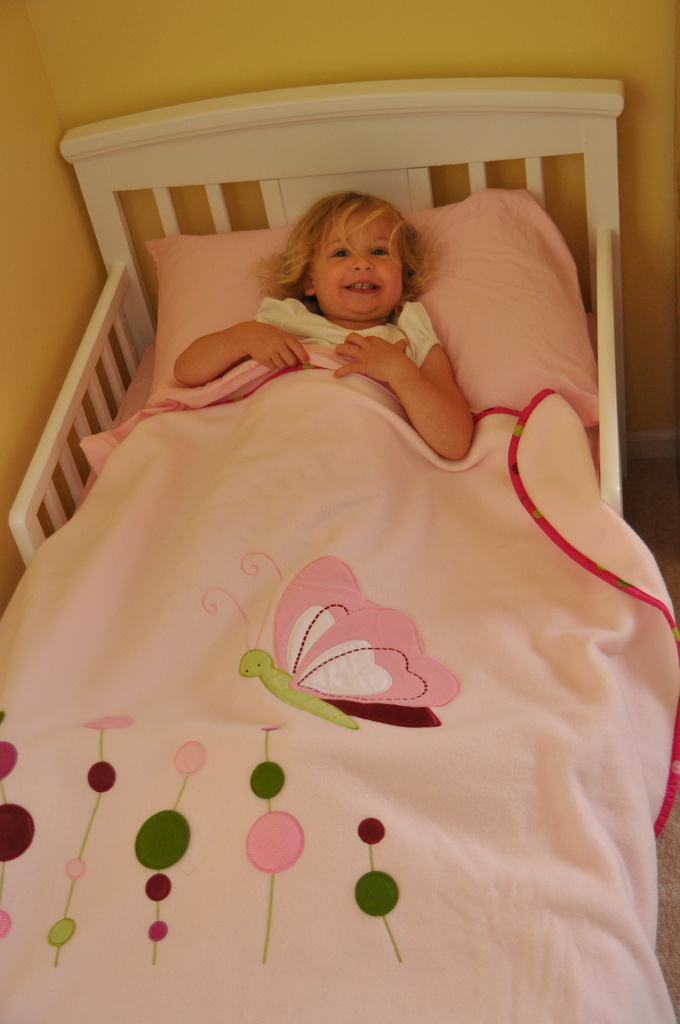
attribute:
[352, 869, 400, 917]
design — green, circular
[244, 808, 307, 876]
design — pink, circular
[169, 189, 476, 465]
child — white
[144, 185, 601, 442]
pillow — pink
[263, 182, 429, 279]
hair — blonde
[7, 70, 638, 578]
bed frame — white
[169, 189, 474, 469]
girl — little, smiling, young, white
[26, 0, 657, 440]
wall — yellow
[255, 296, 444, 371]
shirt — white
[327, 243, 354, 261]
eye — open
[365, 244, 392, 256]
eye — open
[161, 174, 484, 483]
female — young, Caucasian